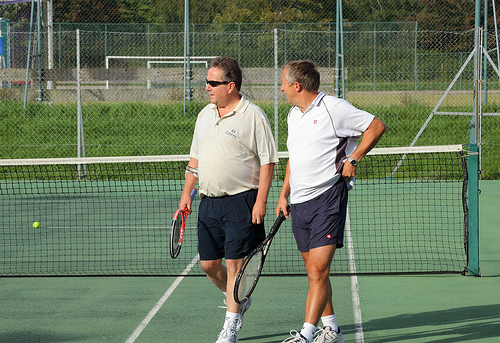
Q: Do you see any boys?
A: No, there are no boys.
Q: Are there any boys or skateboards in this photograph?
A: No, there are no boys or skateboards.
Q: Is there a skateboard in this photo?
A: No, there are no skateboards.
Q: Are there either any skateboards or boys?
A: No, there are no skateboards or boys.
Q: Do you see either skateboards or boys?
A: No, there are no skateboards or boys.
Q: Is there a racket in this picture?
A: Yes, there is a racket.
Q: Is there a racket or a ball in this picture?
A: Yes, there is a racket.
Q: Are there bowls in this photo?
A: No, there are no bowls.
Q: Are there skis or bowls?
A: No, there are no bowls or skis.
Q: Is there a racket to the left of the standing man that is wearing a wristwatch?
A: Yes, there is a racket to the left of the man.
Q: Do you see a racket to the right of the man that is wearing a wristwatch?
A: No, the racket is to the left of the man.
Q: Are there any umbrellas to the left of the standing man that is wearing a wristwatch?
A: No, there is a racket to the left of the man.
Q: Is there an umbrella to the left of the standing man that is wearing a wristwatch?
A: No, there is a racket to the left of the man.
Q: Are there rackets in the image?
A: Yes, there is a racket.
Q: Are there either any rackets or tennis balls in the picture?
A: Yes, there is a racket.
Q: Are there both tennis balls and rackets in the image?
A: Yes, there are both a racket and a tennis ball.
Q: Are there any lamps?
A: No, there are no lamps.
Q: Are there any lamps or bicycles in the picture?
A: No, there are no lamps or bicycles.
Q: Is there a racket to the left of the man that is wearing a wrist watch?
A: Yes, there is a racket to the left of the man.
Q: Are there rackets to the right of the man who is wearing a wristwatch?
A: No, the racket is to the left of the man.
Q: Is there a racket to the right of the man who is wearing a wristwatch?
A: No, the racket is to the left of the man.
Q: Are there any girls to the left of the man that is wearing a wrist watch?
A: No, there is a racket to the left of the man.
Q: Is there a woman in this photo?
A: No, there are no women.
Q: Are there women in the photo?
A: No, there are no women.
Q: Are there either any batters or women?
A: No, there are no women or batters.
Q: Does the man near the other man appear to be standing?
A: Yes, the man is standing.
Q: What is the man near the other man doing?
A: The man is standing.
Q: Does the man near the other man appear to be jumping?
A: No, the man is standing.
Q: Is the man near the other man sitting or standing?
A: The man is standing.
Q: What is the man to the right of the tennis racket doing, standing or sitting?
A: The man is standing.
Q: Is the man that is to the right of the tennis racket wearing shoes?
A: Yes, the man is wearing shoes.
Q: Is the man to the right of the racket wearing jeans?
A: No, the man is wearing shoes.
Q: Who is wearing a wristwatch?
A: The man is wearing a wristwatch.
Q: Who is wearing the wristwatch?
A: The man is wearing a wristwatch.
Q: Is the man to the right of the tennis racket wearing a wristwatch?
A: Yes, the man is wearing a wristwatch.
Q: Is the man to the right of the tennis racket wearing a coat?
A: No, the man is wearing a wristwatch.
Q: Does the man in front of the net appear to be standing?
A: Yes, the man is standing.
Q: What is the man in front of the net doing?
A: The man is standing.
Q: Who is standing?
A: The man is standing.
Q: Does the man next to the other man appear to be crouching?
A: No, the man is standing.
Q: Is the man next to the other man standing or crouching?
A: The man is standing.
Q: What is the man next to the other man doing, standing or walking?
A: The man is standing.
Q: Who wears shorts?
A: The man wears shorts.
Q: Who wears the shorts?
A: The man wears shorts.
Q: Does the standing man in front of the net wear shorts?
A: Yes, the man wears shorts.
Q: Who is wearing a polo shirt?
A: The man is wearing a polo shirt.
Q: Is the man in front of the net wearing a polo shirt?
A: Yes, the man is wearing a polo shirt.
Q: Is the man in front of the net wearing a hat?
A: No, the man is wearing a polo shirt.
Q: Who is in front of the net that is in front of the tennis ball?
A: The man is in front of the net.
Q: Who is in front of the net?
A: The man is in front of the net.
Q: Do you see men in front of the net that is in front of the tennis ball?
A: Yes, there is a man in front of the net.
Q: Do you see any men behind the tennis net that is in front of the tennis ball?
A: No, the man is in front of the net.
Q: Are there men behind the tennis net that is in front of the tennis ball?
A: No, the man is in front of the net.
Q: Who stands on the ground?
A: The man stands on the ground.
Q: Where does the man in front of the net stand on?
A: The man stands on the ground.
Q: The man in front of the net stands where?
A: The man stands on the ground.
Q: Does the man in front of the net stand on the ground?
A: Yes, the man stands on the ground.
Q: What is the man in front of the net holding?
A: The man is holding the tennis racket.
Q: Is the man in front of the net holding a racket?
A: Yes, the man is holding a racket.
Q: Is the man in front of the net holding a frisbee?
A: No, the man is holding a racket.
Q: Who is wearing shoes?
A: The man is wearing shoes.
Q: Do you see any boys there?
A: No, there are no boys.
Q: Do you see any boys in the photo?
A: No, there are no boys.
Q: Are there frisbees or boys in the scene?
A: No, there are no boys or frisbees.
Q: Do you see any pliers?
A: No, there are no pliers.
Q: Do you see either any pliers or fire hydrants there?
A: No, there are no pliers or fire hydrants.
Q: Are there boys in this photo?
A: No, there are no boys.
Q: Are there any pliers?
A: No, there are no pliers.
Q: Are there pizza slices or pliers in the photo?
A: No, there are no pliers or pizza slices.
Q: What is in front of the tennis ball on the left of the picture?
A: The net is in front of the tennis ball.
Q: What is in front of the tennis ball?
A: The net is in front of the tennis ball.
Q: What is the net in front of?
A: The net is in front of the tennis ball.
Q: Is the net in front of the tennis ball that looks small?
A: Yes, the net is in front of the tennis ball.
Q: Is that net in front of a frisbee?
A: No, the net is in front of the tennis ball.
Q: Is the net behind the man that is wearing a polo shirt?
A: Yes, the net is behind the man.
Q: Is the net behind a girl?
A: No, the net is behind the man.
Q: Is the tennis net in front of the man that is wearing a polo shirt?
A: No, the net is behind the man.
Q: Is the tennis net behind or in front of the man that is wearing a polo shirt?
A: The net is behind the man.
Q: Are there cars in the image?
A: No, there are no cars.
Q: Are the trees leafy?
A: Yes, the trees are leafy.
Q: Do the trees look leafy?
A: Yes, the trees are leafy.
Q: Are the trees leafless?
A: No, the trees are leafy.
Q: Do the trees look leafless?
A: No, the trees are leafy.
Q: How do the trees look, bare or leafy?
A: The trees are leafy.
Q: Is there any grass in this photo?
A: Yes, there is grass.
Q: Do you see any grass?
A: Yes, there is grass.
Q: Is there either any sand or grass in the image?
A: Yes, there is grass.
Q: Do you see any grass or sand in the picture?
A: Yes, there is grass.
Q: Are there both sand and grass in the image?
A: No, there is grass but no sand.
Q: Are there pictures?
A: No, there are no pictures.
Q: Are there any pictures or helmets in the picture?
A: No, there are no pictures or helmets.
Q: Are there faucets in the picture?
A: No, there are no faucets.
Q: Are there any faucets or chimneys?
A: No, there are no faucets or chimneys.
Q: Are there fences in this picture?
A: Yes, there is a fence.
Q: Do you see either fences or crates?
A: Yes, there is a fence.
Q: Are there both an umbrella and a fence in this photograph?
A: No, there is a fence but no umbrellas.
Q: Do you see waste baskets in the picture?
A: No, there are no waste baskets.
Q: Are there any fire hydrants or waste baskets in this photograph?
A: No, there are no waste baskets or fire hydrants.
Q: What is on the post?
A: The fence is on the post.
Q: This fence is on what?
A: The fence is on the post.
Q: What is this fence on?
A: The fence is on the post.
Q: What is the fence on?
A: The fence is on the post.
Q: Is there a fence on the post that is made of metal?
A: Yes, there is a fence on the post.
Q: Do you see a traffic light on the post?
A: No, there is a fence on the post.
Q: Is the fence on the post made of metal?
A: Yes, the fence is on the post.